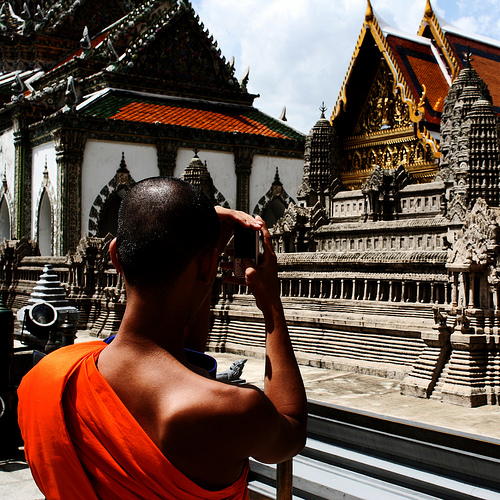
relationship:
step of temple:
[258, 302, 473, 414] [306, 15, 499, 365]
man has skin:
[16, 178, 325, 497] [152, 309, 247, 429]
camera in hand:
[234, 221, 259, 275] [239, 220, 315, 304]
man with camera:
[16, 178, 325, 497] [234, 221, 259, 275]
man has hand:
[16, 178, 325, 497] [239, 220, 315, 304]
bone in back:
[162, 375, 181, 454] [15, 338, 245, 497]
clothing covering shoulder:
[16, 341, 250, 497] [18, 335, 105, 431]